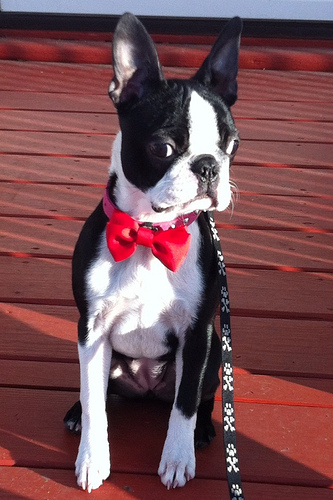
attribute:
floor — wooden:
[240, 49, 326, 487]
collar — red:
[98, 187, 203, 233]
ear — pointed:
[109, 9, 167, 116]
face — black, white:
[133, 98, 238, 216]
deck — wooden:
[2, 35, 327, 497]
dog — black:
[63, 12, 246, 488]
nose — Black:
[192, 157, 225, 183]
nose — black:
[190, 153, 220, 176]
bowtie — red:
[103, 206, 193, 274]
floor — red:
[233, 134, 328, 353]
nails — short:
[159, 469, 180, 498]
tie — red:
[105, 210, 190, 273]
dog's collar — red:
[95, 168, 206, 232]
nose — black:
[189, 147, 219, 181]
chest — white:
[107, 305, 179, 358]